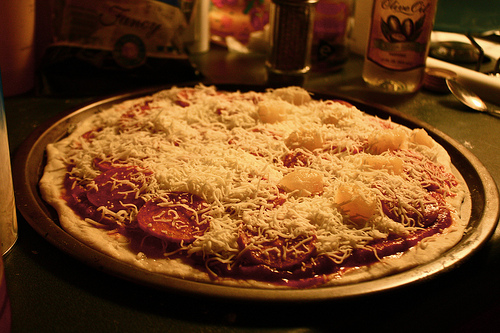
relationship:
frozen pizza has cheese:
[38, 84, 474, 288] [165, 139, 245, 177]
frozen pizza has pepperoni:
[38, 84, 474, 288] [137, 197, 196, 239]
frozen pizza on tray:
[38, 84, 474, 288] [21, 79, 496, 302]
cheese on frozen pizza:
[161, 112, 278, 192] [38, 84, 474, 288]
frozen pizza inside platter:
[38, 84, 474, 288] [323, 89, 498, 299]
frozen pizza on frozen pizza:
[38, 84, 474, 288] [38, 84, 474, 288]